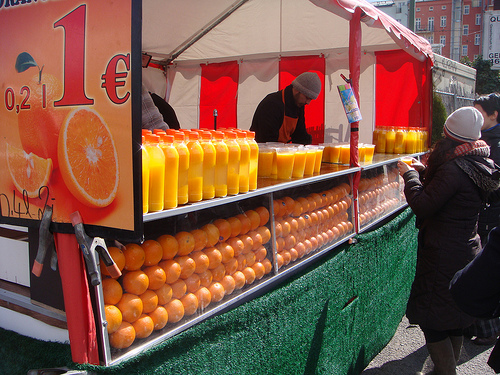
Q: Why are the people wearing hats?
A: Because of the cold.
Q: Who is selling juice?
A: A mobile street vendor.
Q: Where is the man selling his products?
A: In the street.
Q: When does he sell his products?
A: During the day.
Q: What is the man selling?
A: Freshly squeezed orange juice.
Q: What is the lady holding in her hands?
A: A cup of orange juice.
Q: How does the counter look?
A: Clean and well organized.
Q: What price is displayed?
A: 1 euro.